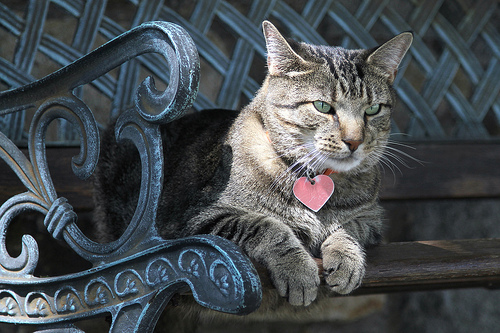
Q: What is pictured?
A: A cat.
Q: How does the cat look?
A: Curious.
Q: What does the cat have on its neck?
A: A heart.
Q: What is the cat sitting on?
A: A bench.